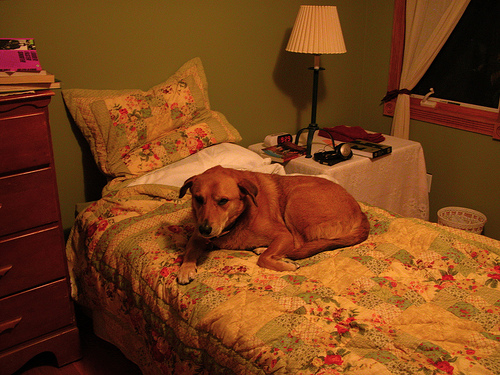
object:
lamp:
[287, 2, 344, 151]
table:
[269, 117, 441, 229]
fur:
[254, 175, 291, 217]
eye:
[192, 193, 206, 204]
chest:
[1, 85, 89, 374]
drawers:
[0, 110, 82, 359]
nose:
[199, 220, 213, 237]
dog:
[166, 161, 371, 292]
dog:
[178, 161, 372, 269]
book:
[259, 142, 303, 163]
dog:
[177, 163, 370, 284]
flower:
[436, 270, 457, 282]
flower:
[331, 317, 352, 334]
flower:
[323, 352, 343, 366]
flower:
[264, 284, 272, 291]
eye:
[215, 195, 227, 206]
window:
[379, 1, 499, 130]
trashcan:
[437, 205, 487, 234]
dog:
[165, 163, 365, 274]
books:
[0, 72, 64, 91]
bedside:
[249, 127, 422, 220]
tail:
[287, 234, 369, 260]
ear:
[173, 174, 197, 199]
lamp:
[288, 4, 348, 156]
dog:
[171, 162, 370, 269]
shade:
[278, 2, 369, 62]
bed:
[67, 130, 500, 374]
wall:
[5, 0, 500, 244]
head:
[181, 177, 246, 230]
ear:
[235, 178, 262, 207]